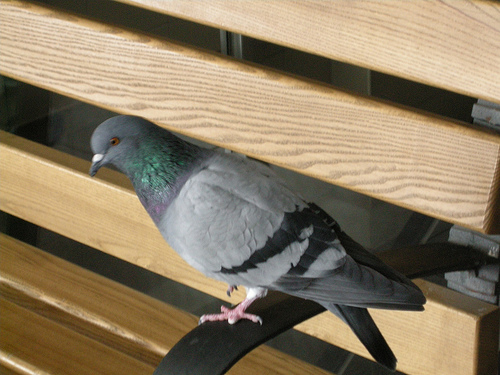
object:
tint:
[122, 138, 212, 210]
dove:
[88, 113, 429, 369]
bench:
[3, 4, 499, 374]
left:
[82, 111, 433, 375]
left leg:
[194, 278, 270, 327]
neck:
[136, 133, 207, 205]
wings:
[223, 161, 426, 370]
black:
[213, 201, 345, 276]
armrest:
[146, 239, 499, 374]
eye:
[109, 136, 122, 146]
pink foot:
[199, 305, 263, 328]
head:
[86, 111, 163, 180]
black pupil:
[111, 139, 116, 144]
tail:
[325, 299, 402, 365]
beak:
[86, 158, 102, 179]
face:
[88, 132, 131, 178]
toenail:
[255, 315, 264, 325]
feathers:
[146, 137, 424, 369]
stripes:
[224, 204, 345, 290]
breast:
[153, 211, 213, 271]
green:
[138, 138, 189, 191]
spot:
[93, 152, 104, 164]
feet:
[196, 297, 265, 327]